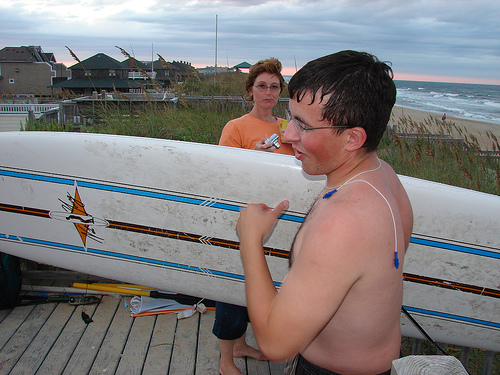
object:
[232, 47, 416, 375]
kid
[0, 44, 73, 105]
houses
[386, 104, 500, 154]
sand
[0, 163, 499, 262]
stripe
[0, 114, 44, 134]
wooden deck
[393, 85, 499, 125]
wave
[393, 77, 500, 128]
water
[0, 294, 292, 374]
boardwalk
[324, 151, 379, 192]
neck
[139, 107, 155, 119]
leaves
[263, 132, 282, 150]
camera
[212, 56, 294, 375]
lady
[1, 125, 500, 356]
surfboard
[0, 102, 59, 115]
guardrail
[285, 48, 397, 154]
hair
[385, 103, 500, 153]
shore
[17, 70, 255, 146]
grass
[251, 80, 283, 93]
glasses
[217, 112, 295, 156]
shirt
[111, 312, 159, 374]
boarding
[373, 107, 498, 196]
bushes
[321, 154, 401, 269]
earplugs